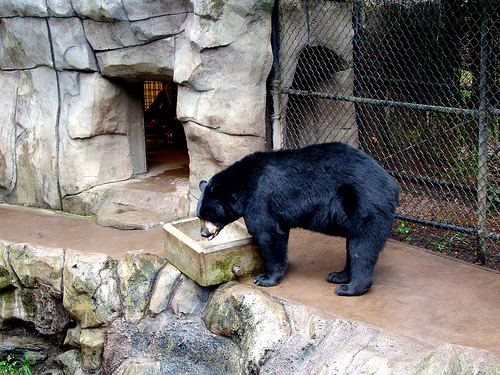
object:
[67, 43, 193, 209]
cave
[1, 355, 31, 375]
bush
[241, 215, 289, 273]
leg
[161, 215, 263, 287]
bin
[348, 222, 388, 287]
leg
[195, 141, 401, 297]
bear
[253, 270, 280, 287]
paw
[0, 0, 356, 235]
rock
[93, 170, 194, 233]
rock step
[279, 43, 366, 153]
entrance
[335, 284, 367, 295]
left paw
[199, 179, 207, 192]
ear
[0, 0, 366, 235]
stone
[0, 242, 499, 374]
stone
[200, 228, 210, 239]
nose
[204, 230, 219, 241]
mouth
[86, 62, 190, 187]
entrance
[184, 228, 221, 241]
water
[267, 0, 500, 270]
fence